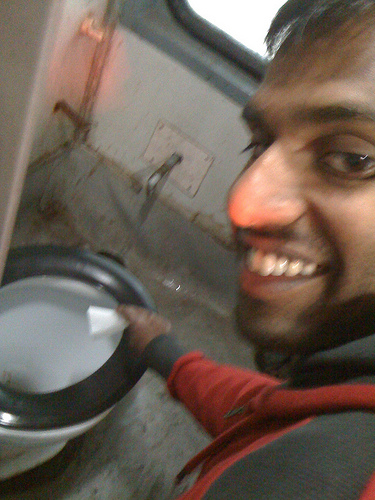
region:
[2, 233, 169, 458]
A toilet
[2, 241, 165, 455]
A black toilet seat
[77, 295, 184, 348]
A white cloth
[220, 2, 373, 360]
A man's face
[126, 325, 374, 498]
A red and gray jacket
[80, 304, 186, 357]
The man's hand holding a cloth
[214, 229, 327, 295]
The man's white-teethed smile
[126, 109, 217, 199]
A plate on the wall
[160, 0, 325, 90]
A corner of a window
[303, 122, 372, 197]
The man's left eye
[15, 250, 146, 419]
One toilet is seen.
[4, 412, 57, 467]
Toilet is white color.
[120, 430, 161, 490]
Floor is grey color.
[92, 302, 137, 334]
Tissue paper is white color.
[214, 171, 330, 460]
One man is seen.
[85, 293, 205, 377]
man is holding tissue paper.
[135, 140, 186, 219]
One tap is seen.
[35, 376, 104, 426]
toilet seat is black color.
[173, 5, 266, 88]
window has black rim.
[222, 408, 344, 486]
man is in red and grey shirt.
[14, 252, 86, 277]
this is the toilet seat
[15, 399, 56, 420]
the toilet seat is black in color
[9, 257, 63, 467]
this is a toilet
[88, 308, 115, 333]
this is a piece of tissue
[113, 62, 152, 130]
this is the toilet wall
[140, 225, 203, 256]
the wall is white in color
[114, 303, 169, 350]
the man is holding some tissue paper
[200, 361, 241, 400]
this is a sweater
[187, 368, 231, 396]
the sweater is red in color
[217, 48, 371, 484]
this is a man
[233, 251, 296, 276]
teeth of a man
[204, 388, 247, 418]
part of a red jumper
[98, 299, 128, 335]
piece of a white tissue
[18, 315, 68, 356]
inner part of a toilet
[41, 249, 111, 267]
black edge of the toilet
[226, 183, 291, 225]
nose of the man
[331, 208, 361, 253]
left cheek of the man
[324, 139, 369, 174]
left eye of the man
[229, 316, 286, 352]
chin of the man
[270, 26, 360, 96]
head of the man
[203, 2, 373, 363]
Man in foreground is smiling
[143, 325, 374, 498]
Man is wearing a red and black jacket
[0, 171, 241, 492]
The floor is gray in color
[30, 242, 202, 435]
Man is touching the toilet lid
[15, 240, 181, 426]
Toilet lid is black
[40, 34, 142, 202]
Rust is on the corner of the room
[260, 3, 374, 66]
Man has dark colored hair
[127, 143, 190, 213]
A pipe is in the background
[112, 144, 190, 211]
The pipe in the background is gray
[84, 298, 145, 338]
Man has a white object in his hand